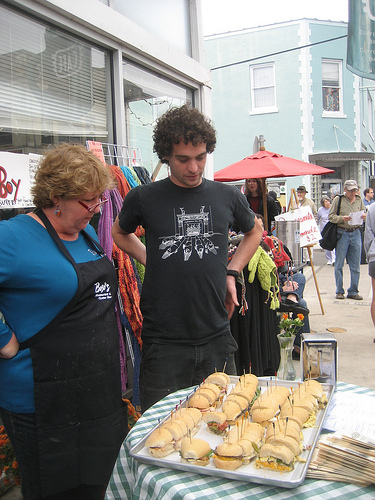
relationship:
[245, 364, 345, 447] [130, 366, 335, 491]
sandwich on pan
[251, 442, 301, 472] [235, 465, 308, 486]
sandwich on tray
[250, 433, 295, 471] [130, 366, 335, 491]
sandwich on pan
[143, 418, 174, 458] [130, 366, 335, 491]
sandwich on pan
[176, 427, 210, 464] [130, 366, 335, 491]
sandwich on pan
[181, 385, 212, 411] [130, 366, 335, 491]
sandwich on pan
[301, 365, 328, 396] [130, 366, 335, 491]
sandwich on pan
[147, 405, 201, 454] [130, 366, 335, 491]
sandwich on pan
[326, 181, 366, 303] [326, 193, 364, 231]
man in shirt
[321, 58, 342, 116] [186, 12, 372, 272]
window on blue house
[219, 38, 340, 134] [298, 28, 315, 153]
building with trim